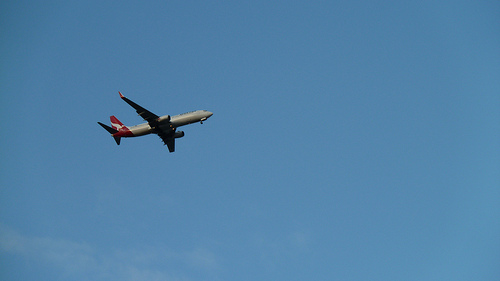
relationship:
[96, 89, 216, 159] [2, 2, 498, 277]
airplane in sky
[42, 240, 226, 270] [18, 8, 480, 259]
clouds in sky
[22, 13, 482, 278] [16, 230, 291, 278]
sky with clouds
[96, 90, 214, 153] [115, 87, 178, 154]
airplane with wings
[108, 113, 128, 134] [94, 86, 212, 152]
tail on plane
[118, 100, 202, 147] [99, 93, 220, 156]
underbelly of plane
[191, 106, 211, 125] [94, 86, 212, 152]
nose of plane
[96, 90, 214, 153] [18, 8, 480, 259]
airplane flying in sky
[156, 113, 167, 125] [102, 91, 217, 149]
engine of plane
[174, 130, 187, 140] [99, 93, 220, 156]
engine of plane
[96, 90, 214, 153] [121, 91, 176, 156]
airplane with wings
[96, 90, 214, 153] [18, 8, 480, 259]
airplane in sky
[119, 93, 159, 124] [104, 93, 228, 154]
wing of plane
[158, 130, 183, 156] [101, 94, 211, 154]
wing of plane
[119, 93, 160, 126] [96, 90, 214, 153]
wing on airplane